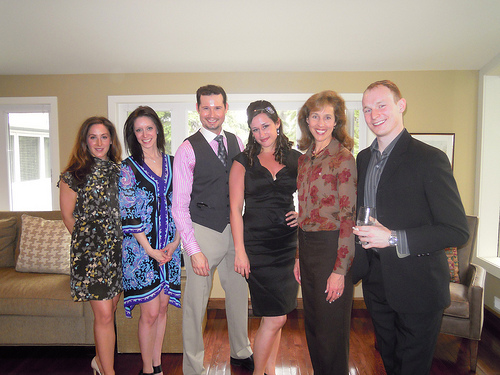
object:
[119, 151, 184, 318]
blue dress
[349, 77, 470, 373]
man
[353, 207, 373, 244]
drink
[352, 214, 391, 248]
hand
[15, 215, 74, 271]
pillow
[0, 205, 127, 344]
couch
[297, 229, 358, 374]
pants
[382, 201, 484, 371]
chair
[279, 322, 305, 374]
floor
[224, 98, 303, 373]
woman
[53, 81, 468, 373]
people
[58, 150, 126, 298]
dress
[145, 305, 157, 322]
knees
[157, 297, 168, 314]
knees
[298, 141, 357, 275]
blouse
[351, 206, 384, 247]
wine glass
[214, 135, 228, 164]
tie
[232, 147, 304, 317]
black dress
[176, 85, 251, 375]
man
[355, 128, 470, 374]
suit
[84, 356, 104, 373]
shoe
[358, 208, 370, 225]
glass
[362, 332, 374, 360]
floor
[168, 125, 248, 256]
long sleeve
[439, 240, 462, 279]
pillow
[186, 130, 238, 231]
suit vest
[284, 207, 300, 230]
hand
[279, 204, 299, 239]
hip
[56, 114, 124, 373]
person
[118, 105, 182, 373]
person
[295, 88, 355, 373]
person